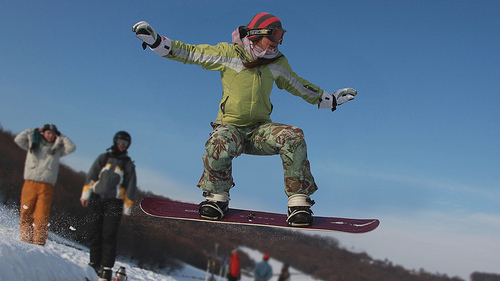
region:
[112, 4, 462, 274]
a snowboarder in the air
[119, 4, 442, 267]
a snowboarder with knees bent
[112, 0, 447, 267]
a snowboarder doing a stunt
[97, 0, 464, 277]
a snowboarder doing a trick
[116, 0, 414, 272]
a snowboarder with a helmet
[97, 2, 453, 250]
a snowboarder with gloves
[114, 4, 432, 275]
a person snowboarding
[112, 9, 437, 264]
a person doing a trick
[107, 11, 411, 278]
a person doing a stunt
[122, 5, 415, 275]
a person with a red helmet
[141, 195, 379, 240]
the board is purple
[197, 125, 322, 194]
the pants are camouflage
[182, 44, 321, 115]
the jacket is green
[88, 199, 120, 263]
the pants are black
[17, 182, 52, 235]
the pants are brown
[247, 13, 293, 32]
the marvin is red and black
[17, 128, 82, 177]
the jacket is grey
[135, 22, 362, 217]
the person is in the air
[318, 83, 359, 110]
the gloves are white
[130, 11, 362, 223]
the hands are spread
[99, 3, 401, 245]
person flying on snowboard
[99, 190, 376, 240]
long purple snowboard in air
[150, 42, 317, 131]
lime green snowboarding jacket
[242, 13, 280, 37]
red and green snow hat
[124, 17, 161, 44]
right white snow glove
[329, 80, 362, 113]
left white snow glove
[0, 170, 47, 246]
burnt orange snowboarding pants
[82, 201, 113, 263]
black snowboarding pants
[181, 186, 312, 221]
black snowboarding boots and bindings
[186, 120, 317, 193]
green and brown snowboarding pants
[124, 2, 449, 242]
snowboarder in mid air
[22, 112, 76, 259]
observer in tan pants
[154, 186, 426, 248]
deep purple colored snow board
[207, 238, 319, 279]
three people in the background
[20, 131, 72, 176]
grey winter jacket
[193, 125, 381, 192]
camouflage colored pants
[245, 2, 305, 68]
black and red colored beanie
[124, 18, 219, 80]
grey gloved hands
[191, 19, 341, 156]
green colored puff jacket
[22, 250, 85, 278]
snow blanketing ground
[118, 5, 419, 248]
The person is jumping on a snowboard.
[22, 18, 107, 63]
The sky is blue.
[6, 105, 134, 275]
Two people standing next to each other.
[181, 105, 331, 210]
The person on the board is wearing pants.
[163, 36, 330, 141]
The person on the board is wearing a jacket.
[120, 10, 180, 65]
A glove is covering the hand.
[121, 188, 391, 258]
The snowboard is a burgundy color.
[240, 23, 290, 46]
The person is wearing goggles.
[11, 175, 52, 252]
The person is wearing orange pants.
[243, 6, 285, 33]
A pink and gray striped hat.